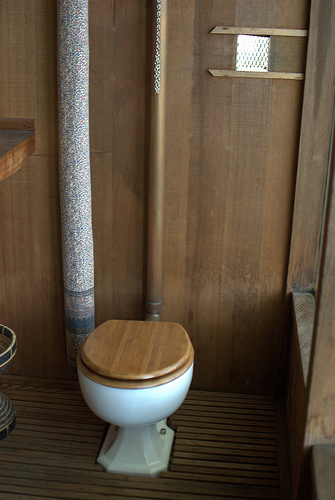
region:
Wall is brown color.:
[204, 99, 274, 183]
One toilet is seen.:
[91, 371, 169, 476]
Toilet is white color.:
[95, 393, 162, 452]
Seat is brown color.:
[102, 352, 150, 388]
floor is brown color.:
[187, 407, 254, 484]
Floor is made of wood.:
[204, 418, 247, 496]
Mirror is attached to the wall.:
[226, 28, 278, 82]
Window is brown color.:
[298, 143, 328, 459]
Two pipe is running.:
[52, 124, 181, 215]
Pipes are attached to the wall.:
[57, 187, 175, 246]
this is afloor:
[14, 441, 92, 477]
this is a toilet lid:
[87, 334, 188, 380]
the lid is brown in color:
[96, 334, 164, 368]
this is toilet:
[74, 335, 188, 477]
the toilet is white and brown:
[77, 323, 186, 472]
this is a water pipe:
[142, 147, 172, 240]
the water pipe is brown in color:
[141, 80, 174, 317]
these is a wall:
[186, 92, 283, 261]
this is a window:
[278, 54, 333, 387]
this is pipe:
[55, 236, 98, 317]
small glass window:
[215, 25, 276, 84]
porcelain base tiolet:
[73, 393, 211, 485]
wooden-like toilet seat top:
[69, 315, 211, 390]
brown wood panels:
[181, 247, 264, 386]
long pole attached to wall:
[50, 40, 99, 302]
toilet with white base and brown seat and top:
[50, 312, 220, 486]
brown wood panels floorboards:
[196, 397, 281, 487]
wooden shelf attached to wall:
[0, 144, 42, 178]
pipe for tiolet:
[131, 18, 174, 308]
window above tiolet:
[197, 14, 292, 97]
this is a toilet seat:
[108, 320, 151, 372]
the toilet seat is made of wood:
[112, 323, 151, 361]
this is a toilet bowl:
[117, 397, 147, 458]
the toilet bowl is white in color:
[114, 397, 152, 458]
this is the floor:
[206, 392, 256, 492]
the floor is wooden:
[195, 406, 265, 498]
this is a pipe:
[150, 33, 161, 313]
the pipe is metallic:
[146, 245, 162, 316]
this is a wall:
[203, 255, 254, 366]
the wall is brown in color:
[191, 252, 269, 283]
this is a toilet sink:
[77, 318, 193, 475]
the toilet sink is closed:
[85, 320, 193, 389]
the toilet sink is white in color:
[83, 391, 183, 420]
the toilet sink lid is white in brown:
[88, 332, 190, 376]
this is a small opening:
[237, 40, 267, 72]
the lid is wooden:
[87, 327, 187, 376]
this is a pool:
[62, 0, 97, 317]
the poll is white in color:
[62, 54, 91, 284]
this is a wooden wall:
[118, 47, 229, 267]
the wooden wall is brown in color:
[181, 86, 273, 309]